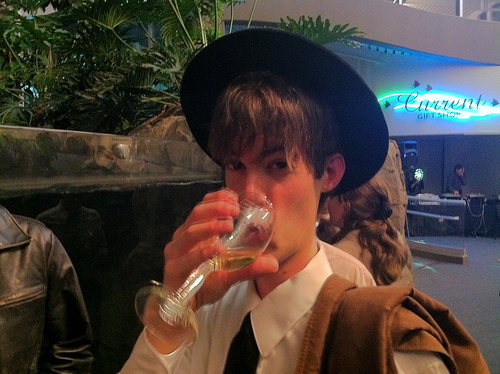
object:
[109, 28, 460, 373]
person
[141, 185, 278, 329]
hand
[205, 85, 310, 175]
bangs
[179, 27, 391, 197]
hat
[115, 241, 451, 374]
shirt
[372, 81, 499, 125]
sign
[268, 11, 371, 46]
plant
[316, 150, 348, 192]
ear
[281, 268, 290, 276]
mole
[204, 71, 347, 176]
hair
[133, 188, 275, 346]
glass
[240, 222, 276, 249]
mouth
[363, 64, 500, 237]
wall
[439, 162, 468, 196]
man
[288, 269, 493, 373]
jacket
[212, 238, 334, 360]
collar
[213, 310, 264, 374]
tie